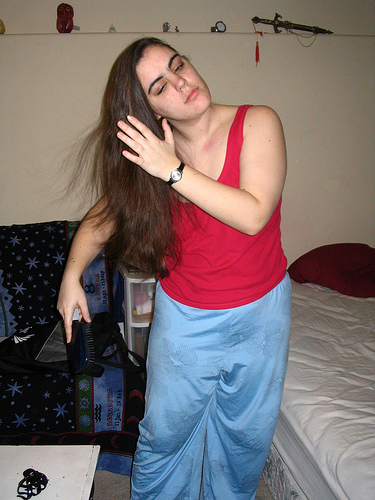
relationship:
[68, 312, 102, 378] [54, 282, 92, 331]
brush in hand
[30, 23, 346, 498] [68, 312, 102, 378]
person holding brush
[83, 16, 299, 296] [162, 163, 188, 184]
woman wearing wristwatch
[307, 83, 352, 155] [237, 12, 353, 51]
wall has a sword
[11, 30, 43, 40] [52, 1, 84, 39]
shelf has a owl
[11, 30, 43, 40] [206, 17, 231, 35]
shelf has a clock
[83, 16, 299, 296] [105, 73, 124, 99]
woman brushing her hair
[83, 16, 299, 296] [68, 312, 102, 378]
woman holding brush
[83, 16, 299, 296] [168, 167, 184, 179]
woman wearing watch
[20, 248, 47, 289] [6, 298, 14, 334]
stars on towel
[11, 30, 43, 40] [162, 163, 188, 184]
shelf has wristwatch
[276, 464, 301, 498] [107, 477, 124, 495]
box spring sits on floor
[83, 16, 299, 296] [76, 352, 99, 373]
woman holding hairbrush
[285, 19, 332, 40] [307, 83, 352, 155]
knife on wall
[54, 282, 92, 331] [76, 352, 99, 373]
hand has hairbrush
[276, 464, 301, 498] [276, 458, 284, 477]
box spring has flowers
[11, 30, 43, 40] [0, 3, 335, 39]
shelf with collectables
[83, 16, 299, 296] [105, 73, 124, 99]
woman brushing hair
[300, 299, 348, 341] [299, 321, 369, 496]
pad cover on bed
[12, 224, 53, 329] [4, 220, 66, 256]
blanket on chair